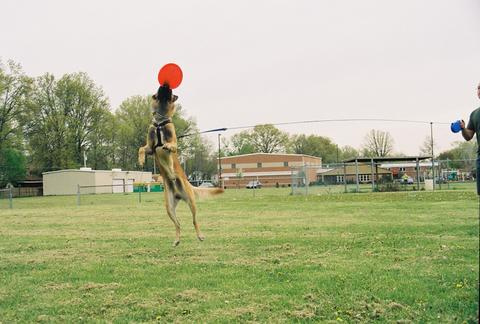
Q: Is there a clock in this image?
A: No, there are no clocks.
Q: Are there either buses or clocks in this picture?
A: No, there are no clocks or buses.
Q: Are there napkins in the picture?
A: No, there are no napkins.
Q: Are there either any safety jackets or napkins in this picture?
A: No, there are no napkins or safety jackets.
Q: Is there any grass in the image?
A: Yes, there is grass.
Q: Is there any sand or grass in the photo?
A: Yes, there is grass.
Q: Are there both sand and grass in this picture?
A: No, there is grass but no sand.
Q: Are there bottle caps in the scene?
A: No, there are no bottle caps.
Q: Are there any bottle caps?
A: No, there are no bottle caps.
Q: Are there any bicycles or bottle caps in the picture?
A: No, there are no bottle caps or bicycles.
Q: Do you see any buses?
A: No, there are no buses.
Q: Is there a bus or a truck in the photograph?
A: No, there are no buses or trucks.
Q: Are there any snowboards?
A: No, there are no snowboards.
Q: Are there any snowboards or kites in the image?
A: No, there are no snowboards or kites.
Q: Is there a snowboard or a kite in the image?
A: No, there are no snowboards or kites.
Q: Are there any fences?
A: Yes, there is a fence.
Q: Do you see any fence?
A: Yes, there is a fence.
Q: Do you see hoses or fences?
A: Yes, there is a fence.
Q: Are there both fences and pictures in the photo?
A: No, there is a fence but no pictures.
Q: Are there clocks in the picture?
A: No, there are no clocks.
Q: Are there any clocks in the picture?
A: No, there are no clocks.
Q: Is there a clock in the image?
A: No, there are no clocks.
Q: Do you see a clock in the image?
A: No, there are no clocks.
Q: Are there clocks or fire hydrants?
A: No, there are no clocks or fire hydrants.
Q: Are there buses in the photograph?
A: No, there are no buses.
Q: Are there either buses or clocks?
A: No, there are no buses or clocks.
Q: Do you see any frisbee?
A: Yes, there is a frisbee.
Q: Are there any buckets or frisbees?
A: Yes, there is a frisbee.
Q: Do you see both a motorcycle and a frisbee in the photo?
A: No, there is a frisbee but no motorcycles.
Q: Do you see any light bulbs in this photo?
A: No, there are no light bulbs.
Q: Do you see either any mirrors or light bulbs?
A: No, there are no light bulbs or mirrors.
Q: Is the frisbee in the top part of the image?
A: Yes, the frisbee is in the top of the image.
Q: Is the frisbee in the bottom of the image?
A: No, the frisbee is in the top of the image.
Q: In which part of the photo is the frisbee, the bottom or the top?
A: The frisbee is in the top of the image.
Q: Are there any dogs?
A: Yes, there is a dog.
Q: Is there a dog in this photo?
A: Yes, there is a dog.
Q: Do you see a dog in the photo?
A: Yes, there is a dog.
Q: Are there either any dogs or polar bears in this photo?
A: Yes, there is a dog.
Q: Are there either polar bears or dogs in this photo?
A: Yes, there is a dog.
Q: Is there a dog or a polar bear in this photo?
A: Yes, there is a dog.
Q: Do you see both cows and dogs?
A: No, there is a dog but no cows.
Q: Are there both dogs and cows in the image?
A: No, there is a dog but no cows.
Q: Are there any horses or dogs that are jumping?
A: Yes, the dog is jumping.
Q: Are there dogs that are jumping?
A: Yes, there is a dog that is jumping.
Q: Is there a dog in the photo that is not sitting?
A: Yes, there is a dog that is jumping.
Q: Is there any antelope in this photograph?
A: No, there are no antelopes.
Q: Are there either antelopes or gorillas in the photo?
A: No, there are no antelopes or gorillas.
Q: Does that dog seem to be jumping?
A: Yes, the dog is jumping.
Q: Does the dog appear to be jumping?
A: Yes, the dog is jumping.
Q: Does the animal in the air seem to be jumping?
A: Yes, the dog is jumping.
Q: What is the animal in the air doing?
A: The dog is jumping.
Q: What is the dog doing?
A: The dog is jumping.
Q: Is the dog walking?
A: No, the dog is jumping.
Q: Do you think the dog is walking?
A: No, the dog is jumping.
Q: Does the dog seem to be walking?
A: No, the dog is jumping.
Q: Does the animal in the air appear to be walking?
A: No, the dog is jumping.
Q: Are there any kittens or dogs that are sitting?
A: No, there is a dog but it is jumping.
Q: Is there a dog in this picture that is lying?
A: No, there is a dog but it is jumping.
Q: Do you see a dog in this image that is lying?
A: No, there is a dog but it is jumping.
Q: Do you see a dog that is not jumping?
A: No, there is a dog but it is jumping.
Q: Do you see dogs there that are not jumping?
A: No, there is a dog but it is jumping.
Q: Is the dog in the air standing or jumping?
A: The dog is jumping.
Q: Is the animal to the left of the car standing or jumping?
A: The dog is jumping.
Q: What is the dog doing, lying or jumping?
A: The dog is jumping.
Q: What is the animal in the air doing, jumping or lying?
A: The dog is jumping.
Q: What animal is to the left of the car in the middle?
A: The animal is a dog.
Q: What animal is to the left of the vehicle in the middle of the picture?
A: The animal is a dog.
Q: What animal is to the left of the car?
A: The animal is a dog.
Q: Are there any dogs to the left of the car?
A: Yes, there is a dog to the left of the car.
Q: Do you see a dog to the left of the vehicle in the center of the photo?
A: Yes, there is a dog to the left of the car.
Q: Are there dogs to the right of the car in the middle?
A: No, the dog is to the left of the car.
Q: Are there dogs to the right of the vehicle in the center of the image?
A: No, the dog is to the left of the car.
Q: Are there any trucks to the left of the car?
A: No, there is a dog to the left of the car.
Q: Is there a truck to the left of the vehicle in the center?
A: No, there is a dog to the left of the car.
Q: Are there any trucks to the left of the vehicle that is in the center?
A: No, there is a dog to the left of the car.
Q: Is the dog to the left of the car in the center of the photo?
A: Yes, the dog is to the left of the car.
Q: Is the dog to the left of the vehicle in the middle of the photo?
A: Yes, the dog is to the left of the car.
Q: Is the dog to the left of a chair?
A: No, the dog is to the left of the car.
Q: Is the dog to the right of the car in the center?
A: No, the dog is to the left of the car.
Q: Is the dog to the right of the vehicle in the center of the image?
A: No, the dog is to the left of the car.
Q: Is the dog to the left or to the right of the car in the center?
A: The dog is to the left of the car.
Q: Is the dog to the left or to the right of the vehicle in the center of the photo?
A: The dog is to the left of the car.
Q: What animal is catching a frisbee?
A: The animal is a dog.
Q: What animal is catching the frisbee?
A: The animal is a dog.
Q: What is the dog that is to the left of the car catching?
A: The dog is catching a frisbee.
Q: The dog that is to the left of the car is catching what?
A: The dog is catching a frisbee.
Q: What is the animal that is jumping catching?
A: The dog is catching a frisbee.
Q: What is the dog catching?
A: The dog is catching a frisbee.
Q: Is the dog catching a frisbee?
A: Yes, the dog is catching a frisbee.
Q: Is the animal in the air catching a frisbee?
A: Yes, the dog is catching a frisbee.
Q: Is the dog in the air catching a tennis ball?
A: No, the dog is catching a frisbee.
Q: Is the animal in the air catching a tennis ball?
A: No, the dog is catching a frisbee.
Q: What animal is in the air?
A: The animal is a dog.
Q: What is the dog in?
A: The dog is in the air.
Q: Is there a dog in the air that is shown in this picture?
A: Yes, there is a dog in the air.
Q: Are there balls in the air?
A: No, there is a dog in the air.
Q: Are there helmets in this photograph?
A: No, there are no helmets.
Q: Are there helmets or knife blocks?
A: No, there are no helmets or knife blocks.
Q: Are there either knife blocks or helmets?
A: No, there are no helmets or knife blocks.